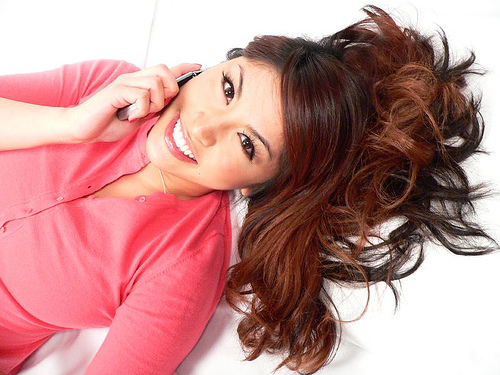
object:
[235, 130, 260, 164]
eyes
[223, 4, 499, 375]
hair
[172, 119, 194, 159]
teeth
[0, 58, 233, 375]
shirt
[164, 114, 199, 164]
lipstick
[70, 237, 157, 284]
sweater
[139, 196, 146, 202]
button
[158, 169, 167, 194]
necklace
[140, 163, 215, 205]
neck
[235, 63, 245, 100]
eyebrow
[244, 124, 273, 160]
eyebrow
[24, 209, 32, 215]
button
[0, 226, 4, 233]
button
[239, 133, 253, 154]
eye ball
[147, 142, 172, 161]
gloss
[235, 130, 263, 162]
lashes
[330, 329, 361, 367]
shadow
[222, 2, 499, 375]
beautiful hair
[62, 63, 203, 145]
hand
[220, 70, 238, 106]
eyes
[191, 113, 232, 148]
woman nose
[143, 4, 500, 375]
head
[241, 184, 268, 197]
ear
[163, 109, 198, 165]
lips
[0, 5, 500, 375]
lady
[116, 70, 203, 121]
phone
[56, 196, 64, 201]
button